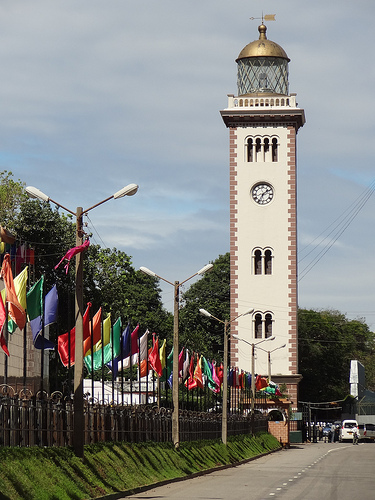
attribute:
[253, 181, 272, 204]
clock — large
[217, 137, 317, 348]
tower — white, brown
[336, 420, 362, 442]
van — white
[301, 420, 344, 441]
people — standing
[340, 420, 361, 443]
vehicle — white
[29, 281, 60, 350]
flag — blue, waving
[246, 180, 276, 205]
clock — large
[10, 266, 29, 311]
flag — yellow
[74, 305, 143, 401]
flag — green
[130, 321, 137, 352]
flag — pink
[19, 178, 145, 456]
street light — double-sided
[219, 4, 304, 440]
building — tall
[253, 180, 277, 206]
clock — large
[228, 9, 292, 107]
top — domed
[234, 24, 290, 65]
dome — golden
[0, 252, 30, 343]
flag — slightly moving, orange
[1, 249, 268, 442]
fence — black, wrought iron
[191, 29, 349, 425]
lighthouse — brick, plastered, white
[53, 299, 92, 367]
flag — red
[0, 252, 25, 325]
flag — orange, colored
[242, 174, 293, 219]
clock — round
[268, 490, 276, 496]
line — white, painted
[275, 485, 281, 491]
line — white, painted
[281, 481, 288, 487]
line — white, painted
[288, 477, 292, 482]
line — white, painted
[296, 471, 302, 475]
line — white, painted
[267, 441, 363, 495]
line — white, dotted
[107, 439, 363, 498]
street — paved, asphalt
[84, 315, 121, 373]
flag — green, flying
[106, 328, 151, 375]
flag — flying, white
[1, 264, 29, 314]
flag — yellow, flying